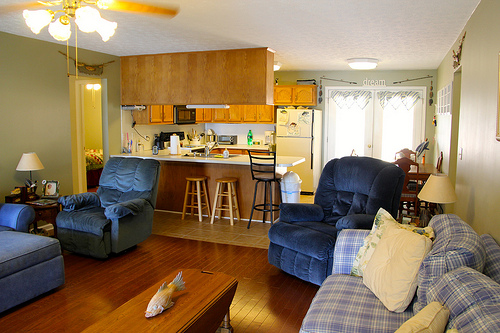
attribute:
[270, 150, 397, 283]
chair — blue, cordoroy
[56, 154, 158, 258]
chair — blue, cordoroy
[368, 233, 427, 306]
pillow — white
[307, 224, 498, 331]
couch — blue, plaid, checkered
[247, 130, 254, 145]
bottle — green, plastic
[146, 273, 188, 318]
fish — statue, decorative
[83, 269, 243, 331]
table — wooden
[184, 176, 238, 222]
stools — wooden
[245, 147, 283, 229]
stool — metal, black, large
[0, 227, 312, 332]
floors — wood, brown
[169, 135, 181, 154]
towels — paper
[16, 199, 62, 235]
table — small, brown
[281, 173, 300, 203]
can — white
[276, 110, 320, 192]
refrigerator — white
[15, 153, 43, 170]
shade — white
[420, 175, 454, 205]
shade — white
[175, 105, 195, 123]
microwave — black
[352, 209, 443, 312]
pillows — white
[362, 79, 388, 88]
word — decor